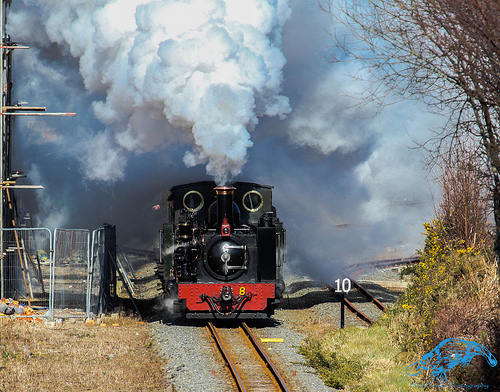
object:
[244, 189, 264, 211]
window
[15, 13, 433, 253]
clouds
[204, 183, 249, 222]
engine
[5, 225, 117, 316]
fence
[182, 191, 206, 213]
window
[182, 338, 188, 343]
rock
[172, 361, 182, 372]
rock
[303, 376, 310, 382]
rock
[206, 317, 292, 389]
tracks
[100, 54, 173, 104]
wall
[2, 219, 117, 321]
gate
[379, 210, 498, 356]
flowers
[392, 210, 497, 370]
bush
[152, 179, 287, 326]
train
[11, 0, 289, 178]
smoke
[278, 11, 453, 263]
cloud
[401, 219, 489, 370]
foliage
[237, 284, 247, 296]
number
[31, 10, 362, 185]
sky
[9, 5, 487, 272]
steam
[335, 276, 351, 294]
10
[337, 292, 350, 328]
pole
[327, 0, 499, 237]
tree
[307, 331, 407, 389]
grass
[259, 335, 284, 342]
bar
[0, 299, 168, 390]
grass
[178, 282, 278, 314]
bumper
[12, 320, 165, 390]
ground.